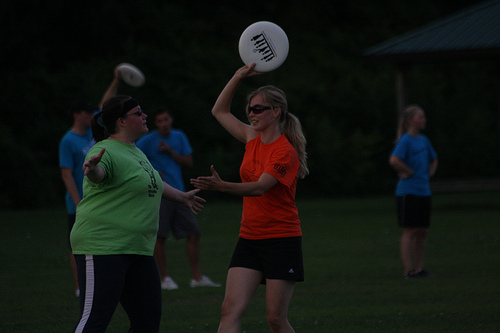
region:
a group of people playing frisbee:
[39, 32, 446, 307]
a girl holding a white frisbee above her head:
[208, 10, 320, 325]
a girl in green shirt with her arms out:
[68, 90, 207, 324]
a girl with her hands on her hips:
[388, 94, 452, 286]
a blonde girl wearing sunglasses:
[213, 80, 315, 178]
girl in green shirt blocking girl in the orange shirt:
[66, 92, 328, 298]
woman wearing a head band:
[83, 89, 166, 163]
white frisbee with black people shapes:
[228, 15, 306, 81]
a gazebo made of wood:
[363, 10, 498, 228]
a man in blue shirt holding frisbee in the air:
[51, 54, 146, 216]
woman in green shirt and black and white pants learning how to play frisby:
[70, 94, 204, 331]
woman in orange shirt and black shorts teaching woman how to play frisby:
[193, 35, 308, 327]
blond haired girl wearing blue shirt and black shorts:
[393, 104, 433, 281]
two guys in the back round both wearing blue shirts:
[58, 105, 223, 287]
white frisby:
[114, 62, 147, 91]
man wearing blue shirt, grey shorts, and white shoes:
[133, 107, 224, 287]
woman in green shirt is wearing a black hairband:
[72, 95, 172, 331]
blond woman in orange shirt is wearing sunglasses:
[196, 61, 313, 326]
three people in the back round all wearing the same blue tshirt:
[63, 100, 434, 288]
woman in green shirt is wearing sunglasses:
[60, 95, 211, 325]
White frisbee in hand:
[235, 16, 287, 71]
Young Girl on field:
[205, 15, 300, 325]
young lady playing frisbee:
[65, 91, 185, 326]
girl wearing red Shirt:
[240, 130, 295, 230]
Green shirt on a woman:
[66, 135, 161, 250]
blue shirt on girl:
[390, 130, 435, 195]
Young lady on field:
[385, 105, 435, 275]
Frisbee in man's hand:
[115, 61, 140, 82]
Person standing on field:
[385, 105, 435, 275]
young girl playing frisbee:
[210, 62, 305, 329]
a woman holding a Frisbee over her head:
[188, 18, 310, 332]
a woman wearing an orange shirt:
[184, 61, 311, 332]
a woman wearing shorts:
[191, 63, 313, 332]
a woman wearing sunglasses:
[188, 59, 312, 331]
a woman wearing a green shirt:
[68, 93, 207, 332]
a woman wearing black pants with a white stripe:
[67, 91, 209, 332]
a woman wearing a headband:
[68, 93, 209, 332]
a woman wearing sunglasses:
[67, 93, 208, 332]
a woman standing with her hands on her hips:
[384, 104, 440, 282]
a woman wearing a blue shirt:
[384, 104, 439, 281]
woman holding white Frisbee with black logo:
[235, 14, 290, 74]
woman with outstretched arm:
[80, 143, 120, 200]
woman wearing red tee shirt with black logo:
[243, 138, 318, 239]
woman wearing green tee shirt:
[88, 140, 171, 264]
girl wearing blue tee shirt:
[385, 128, 441, 208]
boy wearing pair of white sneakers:
[161, 267, 223, 292]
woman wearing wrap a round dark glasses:
[239, 98, 289, 118]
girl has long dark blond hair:
[390, 97, 437, 131]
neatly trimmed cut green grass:
[305, 207, 396, 314]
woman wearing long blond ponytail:
[286, 108, 328, 179]